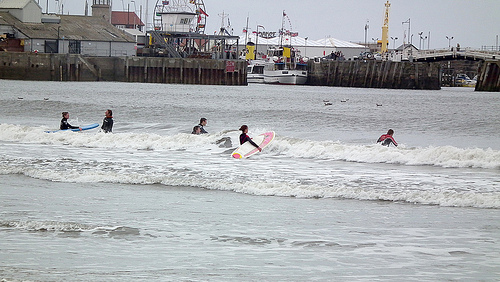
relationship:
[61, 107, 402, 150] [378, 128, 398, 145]
group of surfer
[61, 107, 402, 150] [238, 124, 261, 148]
group of surfer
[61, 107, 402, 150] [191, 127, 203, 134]
group of surfer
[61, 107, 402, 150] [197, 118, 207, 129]
group of surfer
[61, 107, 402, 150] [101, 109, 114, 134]
group of people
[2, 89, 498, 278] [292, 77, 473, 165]
water in water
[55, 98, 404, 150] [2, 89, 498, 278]
people in water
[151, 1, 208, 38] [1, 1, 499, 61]
ferris wheel on pier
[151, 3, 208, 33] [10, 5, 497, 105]
ferris wheel on beach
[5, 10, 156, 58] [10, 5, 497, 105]
house on beach